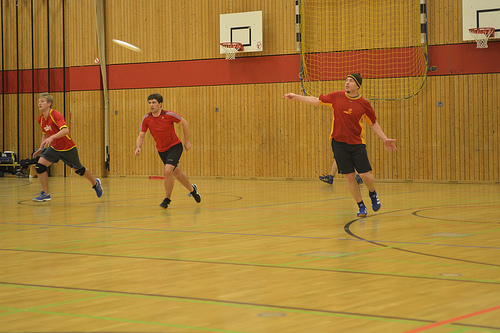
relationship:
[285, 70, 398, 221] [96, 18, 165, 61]
man preparing to catch frisbee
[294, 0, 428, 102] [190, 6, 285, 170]
net hanging on wall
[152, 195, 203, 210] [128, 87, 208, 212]
shoes being worn by player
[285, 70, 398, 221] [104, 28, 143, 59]
man playing with frisbee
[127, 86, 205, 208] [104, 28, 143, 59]
men playing with frisbee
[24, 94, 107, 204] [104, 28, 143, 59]
man playing with frisbee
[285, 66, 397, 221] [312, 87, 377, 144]
man wearing shirt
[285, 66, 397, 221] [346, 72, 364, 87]
man wearing cap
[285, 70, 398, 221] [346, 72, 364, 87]
man wearing cap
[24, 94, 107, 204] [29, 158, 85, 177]
man wearing knee pads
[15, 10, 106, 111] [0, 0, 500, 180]
beams on paneled wall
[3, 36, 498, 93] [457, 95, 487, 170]
line on wall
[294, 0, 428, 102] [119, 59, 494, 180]
net on wall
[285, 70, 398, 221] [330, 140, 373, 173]
man wearing shorts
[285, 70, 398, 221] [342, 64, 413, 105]
man wearing cap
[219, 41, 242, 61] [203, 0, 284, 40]
basketball hoop with backboard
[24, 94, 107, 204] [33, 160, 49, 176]
man wearing guards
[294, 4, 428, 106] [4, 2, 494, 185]
net on wall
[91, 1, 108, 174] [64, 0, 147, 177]
curtain in wall